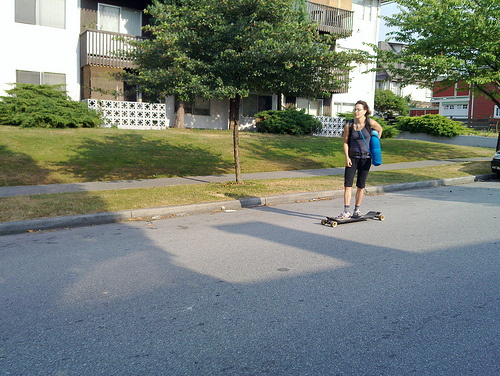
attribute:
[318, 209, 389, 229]
skateboard — black, white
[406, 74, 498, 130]
building — multi-story, red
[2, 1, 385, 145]
building — white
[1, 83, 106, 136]
bush — green